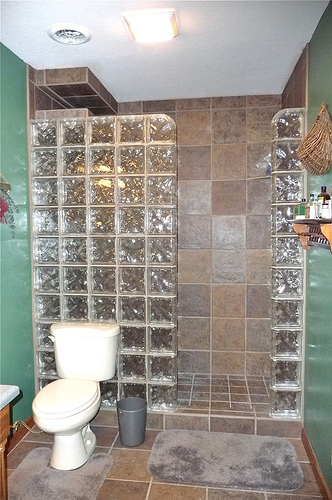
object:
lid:
[50, 322, 119, 337]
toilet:
[32, 320, 121, 471]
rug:
[10, 446, 114, 499]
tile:
[150, 379, 178, 406]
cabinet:
[0, 416, 12, 498]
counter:
[0, 383, 20, 408]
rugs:
[146, 429, 304, 495]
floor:
[5, 373, 328, 499]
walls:
[0, 41, 66, 425]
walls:
[282, 0, 332, 499]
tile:
[274, 389, 302, 416]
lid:
[31, 376, 99, 417]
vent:
[46, 24, 91, 45]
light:
[119, 7, 179, 45]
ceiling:
[0, 0, 332, 103]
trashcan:
[114, 394, 147, 446]